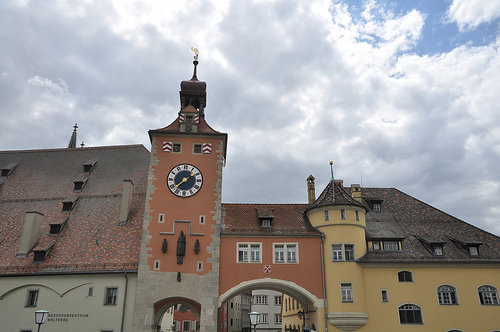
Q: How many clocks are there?
A: One.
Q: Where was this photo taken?
A: London.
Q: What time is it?
A: 1:37 p.m.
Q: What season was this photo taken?
A: Fall.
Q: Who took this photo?
A: A tourist.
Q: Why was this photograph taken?
A: For a magazine.